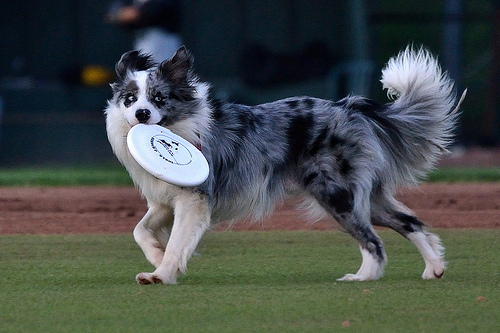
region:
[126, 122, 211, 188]
a white frisbee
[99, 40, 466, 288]
black and white dog carrying frisbee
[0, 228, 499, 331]
grass surrounding dog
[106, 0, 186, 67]
blurry figure of person behind dog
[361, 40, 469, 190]
bushy tail of dog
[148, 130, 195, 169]
black logo and writing on frisbee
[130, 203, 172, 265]
bent front leg of dog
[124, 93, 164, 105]
white eyes of dog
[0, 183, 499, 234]
patch of dirt behind dog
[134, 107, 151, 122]
black nose of dog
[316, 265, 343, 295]
part of a lawn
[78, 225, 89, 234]
part of a field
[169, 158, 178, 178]
part of a floater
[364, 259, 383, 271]
leg of a dog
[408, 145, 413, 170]
tail of a dog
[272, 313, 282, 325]
part of a field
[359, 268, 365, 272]
leg of a dog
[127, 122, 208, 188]
The frisbee is being used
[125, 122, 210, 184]
The frisbee is white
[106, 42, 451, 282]
Dog outside playing with frisbee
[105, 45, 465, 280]
Dog is white, gray and black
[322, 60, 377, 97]
A white chair sitting outside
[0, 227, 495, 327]
Grass is short and green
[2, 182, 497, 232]
Dirt in the ground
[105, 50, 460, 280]
Dog is running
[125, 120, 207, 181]
Frisbee is in the dog's mouth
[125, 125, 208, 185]
Frisbee has words on it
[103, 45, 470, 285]
A black and white dog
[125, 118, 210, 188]
A white frisbee in a dog's mouth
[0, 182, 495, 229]
A small dirt path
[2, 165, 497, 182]
A grassy field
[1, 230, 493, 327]
A grassy field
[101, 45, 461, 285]
A dog holding a frisbee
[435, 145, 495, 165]
A small dirt area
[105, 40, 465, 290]
A dog running around a field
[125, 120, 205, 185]
A frisbee in a dog's mouth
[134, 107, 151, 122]
the wet, black nose of a dog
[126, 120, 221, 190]
White frisbee in dog's mouth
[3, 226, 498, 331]
Trimmed green grass under dog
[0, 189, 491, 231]
Red clay behind the dog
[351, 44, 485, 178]
Bushy white tail of dof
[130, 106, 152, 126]
Small shiny black dog nose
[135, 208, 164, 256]
White paw of dog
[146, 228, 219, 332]
White paw of dog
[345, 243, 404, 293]
White paw of dog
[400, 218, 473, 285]
White paw of dog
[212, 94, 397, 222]
Gray and black coat of dog